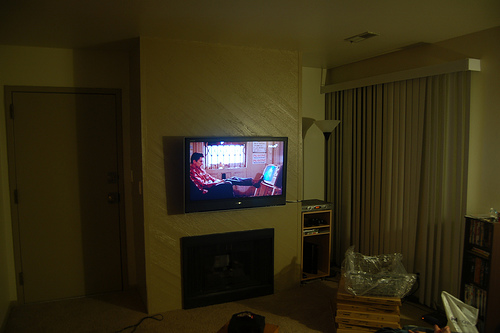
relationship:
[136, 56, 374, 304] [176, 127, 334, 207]
wall behind tv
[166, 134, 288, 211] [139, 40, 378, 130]
televeision hanging on wall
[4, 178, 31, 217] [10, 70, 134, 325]
hinges attached to door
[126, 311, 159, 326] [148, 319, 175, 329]
cable on floor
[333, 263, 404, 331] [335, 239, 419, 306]
boxes with packaging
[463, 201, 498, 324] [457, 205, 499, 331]
items on shelf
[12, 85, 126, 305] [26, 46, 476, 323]
door to room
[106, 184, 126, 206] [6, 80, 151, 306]
door knob on door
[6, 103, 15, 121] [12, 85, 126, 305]
hinge on door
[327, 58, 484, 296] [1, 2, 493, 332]
blinds in room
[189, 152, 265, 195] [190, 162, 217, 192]
man in shirt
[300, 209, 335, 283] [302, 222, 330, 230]
entertainment center in shelf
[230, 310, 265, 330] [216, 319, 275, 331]
object in table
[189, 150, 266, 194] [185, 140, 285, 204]
man in screen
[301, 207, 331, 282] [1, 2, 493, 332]
shelf in room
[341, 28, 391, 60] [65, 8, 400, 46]
air vent in ceiling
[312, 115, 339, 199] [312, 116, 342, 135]
lamp with shade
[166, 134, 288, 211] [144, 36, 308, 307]
televeision on wall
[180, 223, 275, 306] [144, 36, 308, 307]
fireplace in wall